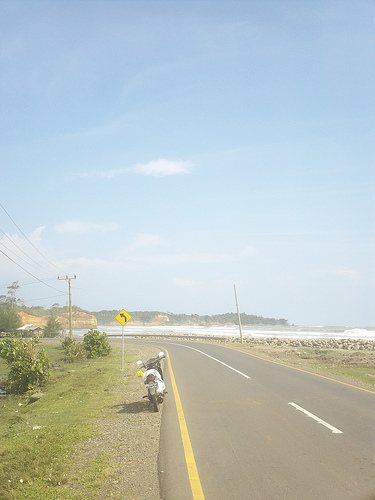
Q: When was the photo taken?
A: Daytime.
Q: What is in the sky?
A: Clouds.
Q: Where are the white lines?
A: Middle of the road.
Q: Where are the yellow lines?
A: Sides of the street.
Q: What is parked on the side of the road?
A: Motorcycle.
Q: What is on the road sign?
A: Arrow.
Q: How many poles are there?
A: Two.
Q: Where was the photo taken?
A: On the road.